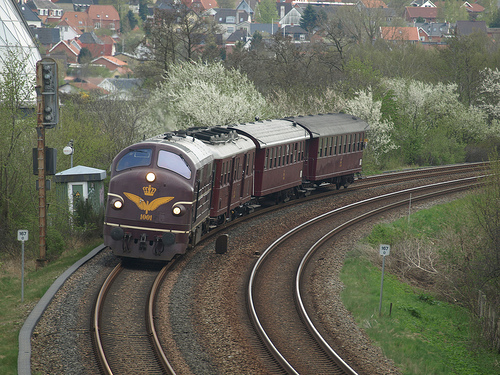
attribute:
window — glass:
[160, 144, 188, 175]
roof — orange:
[88, 54, 125, 64]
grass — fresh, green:
[384, 224, 456, 354]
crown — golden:
[140, 180, 157, 201]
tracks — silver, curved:
[237, 176, 497, 373]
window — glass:
[109, 145, 154, 172]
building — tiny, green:
[50, 163, 105, 235]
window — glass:
[287, 140, 312, 172]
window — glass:
[356, 132, 364, 151]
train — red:
[66, 77, 428, 307]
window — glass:
[352, 137, 372, 156]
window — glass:
[272, 159, 278, 167]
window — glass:
[279, 157, 284, 165]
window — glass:
[296, 153, 300, 161]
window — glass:
[332, 146, 339, 157]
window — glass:
[357, 142, 363, 152]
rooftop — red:
[401, 6, 445, 16]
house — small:
[404, 4, 450, 21]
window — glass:
[220, 163, 229, 187]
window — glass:
[264, 143, 274, 173]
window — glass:
[271, 145, 279, 168]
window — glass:
[283, 145, 293, 167]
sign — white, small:
[18, 227, 29, 242]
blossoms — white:
[194, 82, 240, 120]